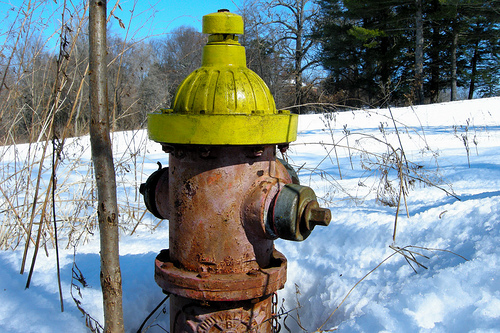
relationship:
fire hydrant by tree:
[138, 8, 331, 333] [68, 101, 147, 298]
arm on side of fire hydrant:
[268, 183, 332, 242] [138, 10, 329, 331]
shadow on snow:
[59, 248, 161, 298] [0, 96, 499, 331]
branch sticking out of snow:
[334, 131, 464, 207] [0, 96, 499, 331]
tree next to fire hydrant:
[85, 1, 125, 333] [138, 10, 329, 331]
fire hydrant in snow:
[138, 10, 329, 331] [0, 96, 499, 331]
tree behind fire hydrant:
[269, 0, 323, 107] [138, 10, 329, 331]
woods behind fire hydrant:
[0, 1, 498, 145] [138, 10, 329, 331]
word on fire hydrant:
[216, 311, 252, 323] [138, 10, 329, 331]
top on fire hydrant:
[145, 8, 299, 145] [138, 10, 329, 331]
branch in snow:
[334, 131, 464, 207] [0, 96, 499, 331]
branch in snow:
[389, 240, 430, 273] [0, 96, 499, 331]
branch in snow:
[364, 156, 459, 202] [10, 89, 484, 323]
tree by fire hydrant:
[84, 1, 128, 327] [138, 8, 331, 333]